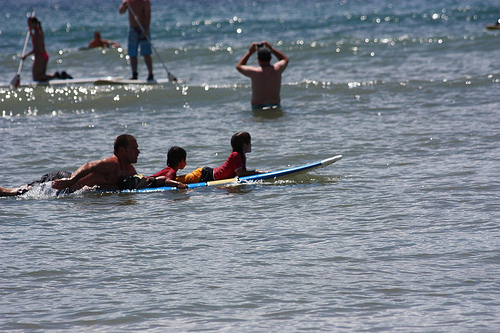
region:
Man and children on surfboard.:
[0, 128, 347, 199]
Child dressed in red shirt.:
[210, 150, 245, 182]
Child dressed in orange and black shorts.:
[183, 163, 216, 184]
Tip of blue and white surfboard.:
[275, 151, 347, 176]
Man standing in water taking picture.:
[232, 37, 294, 106]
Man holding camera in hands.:
[248, 38, 273, 51]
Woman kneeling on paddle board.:
[9, 10, 92, 93]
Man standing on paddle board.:
[91, 3, 181, 89]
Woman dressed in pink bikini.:
[13, 12, 53, 67]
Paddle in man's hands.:
[125, 0, 180, 86]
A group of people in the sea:
[0, 0, 498, 332]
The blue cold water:
[2, 0, 498, 331]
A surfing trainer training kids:
[2, 128, 343, 198]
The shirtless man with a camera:
[237, 42, 292, 112]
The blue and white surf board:
[109, 154, 341, 193]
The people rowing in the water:
[0, 1, 175, 93]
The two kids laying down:
[147, 131, 254, 186]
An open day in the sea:
[1, 0, 498, 332]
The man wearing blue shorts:
[125, 0, 153, 82]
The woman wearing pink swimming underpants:
[26, 14, 71, 84]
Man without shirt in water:
[231, 33, 311, 122]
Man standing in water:
[234, 31, 297, 130]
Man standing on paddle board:
[111, 3, 188, 99]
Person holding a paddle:
[4, 6, 60, 103]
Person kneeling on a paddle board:
[10, 11, 81, 97]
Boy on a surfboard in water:
[207, 124, 349, 192]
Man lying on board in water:
[60, 127, 169, 203]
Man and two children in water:
[64, 113, 351, 215]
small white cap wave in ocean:
[334, 71, 424, 93]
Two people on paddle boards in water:
[0, 1, 194, 97]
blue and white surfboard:
[122, 148, 338, 203]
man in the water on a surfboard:
[5, 135, 151, 202]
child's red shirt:
[215, 150, 249, 178]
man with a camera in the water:
[235, 40, 296, 112]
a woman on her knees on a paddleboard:
[7, 13, 82, 93]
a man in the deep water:
[76, 28, 115, 57]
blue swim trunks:
[127, 27, 152, 55]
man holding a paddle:
[127, 4, 184, 87]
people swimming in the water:
[2, 3, 347, 195]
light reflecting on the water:
[5, 4, 497, 121]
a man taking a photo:
[226, 32, 295, 114]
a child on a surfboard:
[184, 126, 259, 187]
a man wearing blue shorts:
[110, 2, 198, 96]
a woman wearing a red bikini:
[9, 11, 66, 101]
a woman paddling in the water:
[6, 10, 78, 112]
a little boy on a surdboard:
[146, 138, 188, 191]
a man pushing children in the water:
[36, 127, 151, 199]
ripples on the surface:
[271, 209, 396, 295]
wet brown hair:
[230, 132, 242, 141]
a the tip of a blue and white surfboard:
[266, 149, 349, 181]